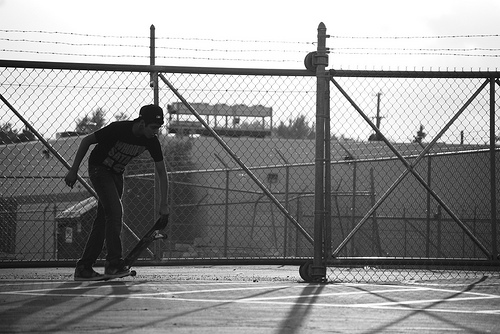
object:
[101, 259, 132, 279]
shoes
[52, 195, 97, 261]
dumpster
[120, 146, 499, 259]
fence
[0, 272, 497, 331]
shadow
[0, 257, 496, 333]
ground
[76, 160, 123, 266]
jeans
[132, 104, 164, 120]
black cap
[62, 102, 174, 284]
boy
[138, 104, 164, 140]
head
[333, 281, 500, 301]
lines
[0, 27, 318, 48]
barbed wire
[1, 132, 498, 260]
building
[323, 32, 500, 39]
wire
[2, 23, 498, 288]
fence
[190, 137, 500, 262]
wall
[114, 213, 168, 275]
skate board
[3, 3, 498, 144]
gray sky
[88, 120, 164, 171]
shirt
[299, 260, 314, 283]
wheel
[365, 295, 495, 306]
line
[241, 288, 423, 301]
line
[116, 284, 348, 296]
line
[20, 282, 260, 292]
line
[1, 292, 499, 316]
line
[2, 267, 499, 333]
blacktop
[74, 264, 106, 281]
man's feet